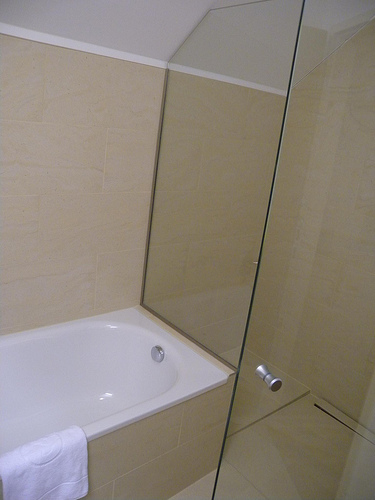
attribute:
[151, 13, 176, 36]
ceiling — white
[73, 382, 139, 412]
tub — white, clean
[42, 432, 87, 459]
towel — white, clean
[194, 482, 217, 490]
floor — off white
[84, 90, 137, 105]
wall — tile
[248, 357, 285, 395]
knob — gray